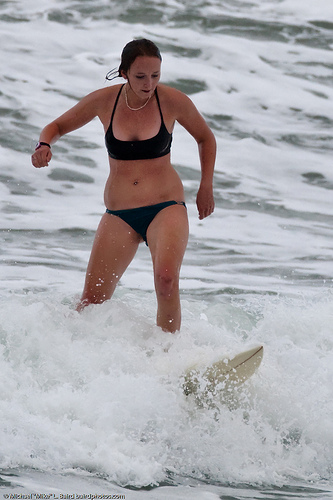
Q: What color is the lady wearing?
A: Black.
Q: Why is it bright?
A: Day time.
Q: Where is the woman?
A: At beach.